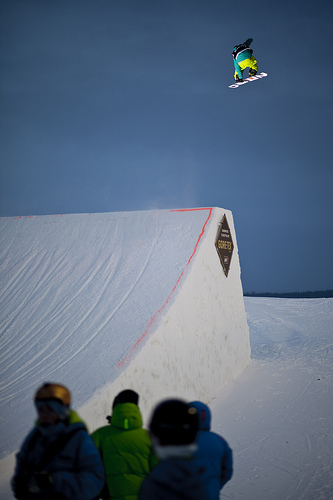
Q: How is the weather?
A: It is clear.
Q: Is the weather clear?
A: Yes, it is clear.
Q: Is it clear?
A: Yes, it is clear.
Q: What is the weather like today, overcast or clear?
A: It is clear.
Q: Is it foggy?
A: No, it is clear.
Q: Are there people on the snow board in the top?
A: Yes, there is a person on the snowboard.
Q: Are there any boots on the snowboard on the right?
A: No, there is a person on the snowboard.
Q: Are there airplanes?
A: No, there are no airplanes.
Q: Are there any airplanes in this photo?
A: No, there are no airplanes.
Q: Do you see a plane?
A: No, there are no airplanes.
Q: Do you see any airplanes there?
A: No, there are no airplanes.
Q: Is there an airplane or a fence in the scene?
A: No, there are no airplanes or fences.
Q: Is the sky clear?
A: Yes, the sky is clear.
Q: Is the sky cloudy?
A: No, the sky is clear.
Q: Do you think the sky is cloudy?
A: No, the sky is clear.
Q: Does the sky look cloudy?
A: No, the sky is clear.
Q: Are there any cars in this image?
A: No, there are no cars.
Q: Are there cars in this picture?
A: No, there are no cars.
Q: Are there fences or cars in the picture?
A: No, there are no cars or fences.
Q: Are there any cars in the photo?
A: No, there are no cars.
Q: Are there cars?
A: No, there are no cars.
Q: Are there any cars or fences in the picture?
A: No, there are no cars or fences.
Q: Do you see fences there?
A: No, there are no fences.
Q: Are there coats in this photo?
A: Yes, there is a coat.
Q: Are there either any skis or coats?
A: Yes, there is a coat.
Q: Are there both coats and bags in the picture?
A: No, there is a coat but no bags.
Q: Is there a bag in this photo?
A: No, there are no bags.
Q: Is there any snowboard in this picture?
A: Yes, there is a snowboard.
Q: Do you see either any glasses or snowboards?
A: Yes, there is a snowboard.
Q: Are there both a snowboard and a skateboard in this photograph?
A: No, there is a snowboard but no skateboards.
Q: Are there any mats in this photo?
A: No, there are no mats.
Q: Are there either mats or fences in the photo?
A: No, there are no mats or fences.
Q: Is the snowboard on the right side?
A: Yes, the snowboard is on the right of the image.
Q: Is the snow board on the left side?
A: No, the snow board is on the right of the image.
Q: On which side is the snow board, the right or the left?
A: The snow board is on the right of the image.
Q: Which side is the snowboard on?
A: The snowboard is on the right of the image.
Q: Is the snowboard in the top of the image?
A: Yes, the snowboard is in the top of the image.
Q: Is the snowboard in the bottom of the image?
A: No, the snowboard is in the top of the image.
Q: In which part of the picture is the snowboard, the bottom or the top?
A: The snowboard is in the top of the image.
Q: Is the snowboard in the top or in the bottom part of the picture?
A: The snowboard is in the top of the image.